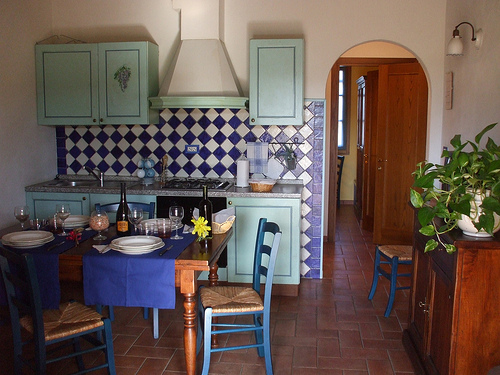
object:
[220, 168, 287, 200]
basket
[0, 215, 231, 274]
table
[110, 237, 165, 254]
plate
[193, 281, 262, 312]
seat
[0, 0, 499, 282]
wall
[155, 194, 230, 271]
oven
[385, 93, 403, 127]
ground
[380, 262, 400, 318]
legs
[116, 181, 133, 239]
stemmed glass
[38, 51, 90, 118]
drawers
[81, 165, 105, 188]
tap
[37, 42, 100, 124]
cabinet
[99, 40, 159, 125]
cabinet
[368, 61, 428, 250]
door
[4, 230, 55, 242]
plate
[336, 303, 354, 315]
tile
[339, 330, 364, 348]
tile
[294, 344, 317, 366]
tile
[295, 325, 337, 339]
tile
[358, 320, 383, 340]
tile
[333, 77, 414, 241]
room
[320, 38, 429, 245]
arched walkway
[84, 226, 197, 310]
cloth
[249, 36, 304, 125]
cabinet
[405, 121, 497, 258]
flower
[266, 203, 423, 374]
floor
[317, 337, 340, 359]
tile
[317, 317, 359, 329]
tile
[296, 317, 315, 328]
tile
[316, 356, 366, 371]
tile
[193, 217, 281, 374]
chair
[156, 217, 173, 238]
glass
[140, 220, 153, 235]
glass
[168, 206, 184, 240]
glass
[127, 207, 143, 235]
glass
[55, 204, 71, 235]
glass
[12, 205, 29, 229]
glass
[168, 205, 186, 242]
wine glasses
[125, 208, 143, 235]
wine glasses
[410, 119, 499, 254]
plant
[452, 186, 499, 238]
pot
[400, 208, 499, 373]
stand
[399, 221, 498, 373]
cabinet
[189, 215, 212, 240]
flower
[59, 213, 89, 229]
white plates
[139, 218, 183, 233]
white plates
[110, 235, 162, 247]
plate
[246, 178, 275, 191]
basket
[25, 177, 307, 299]
counter